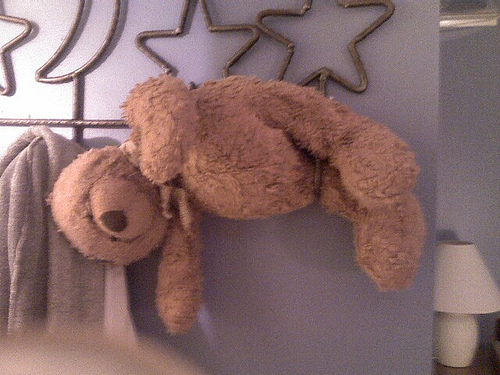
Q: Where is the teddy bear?
A: Hanging on the wall.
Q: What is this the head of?
A: A teddy bear.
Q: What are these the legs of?
A: A teddy bear.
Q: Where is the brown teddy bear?
A: On the wall.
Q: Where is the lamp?
A: In the room.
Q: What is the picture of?
A: A brown Teddy bear.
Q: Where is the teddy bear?
A: Hanging on the wall.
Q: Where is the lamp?
A: On a nightsatnd.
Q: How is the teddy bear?
A: Old and worn out.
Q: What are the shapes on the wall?
A: Stars and a half moon.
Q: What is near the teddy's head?
A: A sweater hanging on a hook.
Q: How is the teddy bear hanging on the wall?
A: Hanging on a metal rod attached to the wall.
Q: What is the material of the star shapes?
A: Metal rods.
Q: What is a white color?
A: A night lamp.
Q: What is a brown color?
A: A teddy bear.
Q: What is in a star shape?
A: A metal rod.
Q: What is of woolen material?
A: A cloth.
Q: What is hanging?
A: A teddy bear.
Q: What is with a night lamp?
A: A table.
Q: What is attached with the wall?
A: A teddy bear.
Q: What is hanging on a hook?
A: A teddy bear.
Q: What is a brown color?
A: Teddy bear.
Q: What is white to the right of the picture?
A: A small lamp.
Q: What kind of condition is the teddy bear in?
A: Like it has seen better days.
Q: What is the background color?
A: Pale lavender.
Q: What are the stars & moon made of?
A: Iron.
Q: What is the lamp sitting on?
A: A table.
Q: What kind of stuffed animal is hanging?
A: A giant teddy bear.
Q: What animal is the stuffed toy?
A: A bear.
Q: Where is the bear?
A: On the wall.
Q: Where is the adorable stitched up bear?
A: Hanging on the wall.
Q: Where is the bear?
A: Hanging on a wal.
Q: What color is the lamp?
A: White.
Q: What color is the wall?
A: Lavender.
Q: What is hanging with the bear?
A: Jacket.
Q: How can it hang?
A: Hooks.